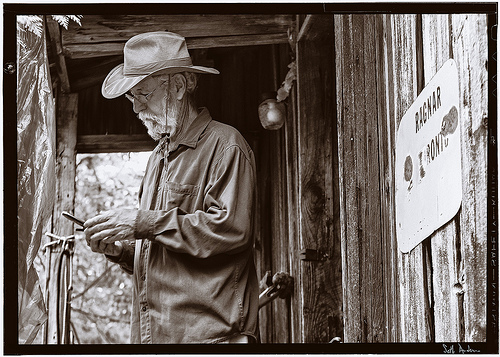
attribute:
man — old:
[95, 37, 254, 347]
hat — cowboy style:
[97, 29, 210, 88]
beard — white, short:
[139, 107, 178, 136]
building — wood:
[237, 16, 499, 315]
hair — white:
[177, 72, 199, 90]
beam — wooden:
[58, 94, 75, 315]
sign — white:
[369, 63, 465, 223]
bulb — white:
[265, 102, 281, 119]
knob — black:
[160, 132, 168, 136]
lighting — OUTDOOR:
[245, 78, 301, 136]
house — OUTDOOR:
[222, 72, 477, 352]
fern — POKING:
[445, 270, 476, 297]